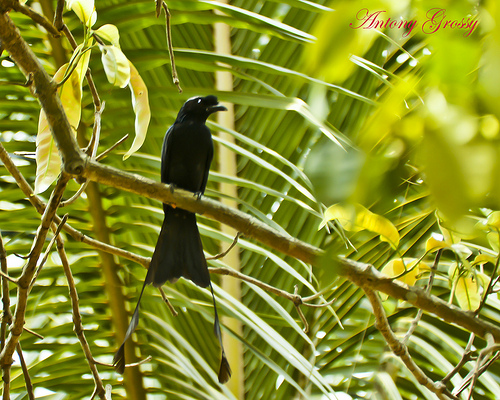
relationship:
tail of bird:
[144, 217, 212, 293] [94, 67, 286, 391]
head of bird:
[175, 93, 227, 123] [112, 92, 234, 385]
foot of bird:
[166, 182, 177, 194] [112, 92, 234, 385]